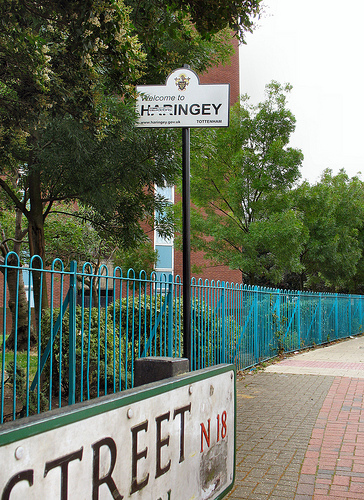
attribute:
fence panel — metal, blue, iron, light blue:
[4, 244, 363, 430]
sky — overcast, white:
[236, 0, 363, 210]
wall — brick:
[1, 1, 243, 349]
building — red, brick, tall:
[2, 1, 246, 355]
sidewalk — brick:
[147, 334, 363, 496]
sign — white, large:
[118, 62, 239, 136]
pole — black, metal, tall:
[178, 125, 198, 367]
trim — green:
[133, 69, 231, 129]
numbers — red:
[215, 411, 227, 443]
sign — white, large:
[5, 359, 237, 499]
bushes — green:
[37, 293, 355, 392]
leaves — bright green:
[0, 0, 267, 210]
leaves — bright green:
[186, 80, 308, 272]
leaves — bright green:
[271, 170, 362, 296]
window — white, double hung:
[149, 142, 177, 295]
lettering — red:
[200, 409, 230, 451]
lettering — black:
[139, 94, 226, 126]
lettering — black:
[3, 397, 197, 499]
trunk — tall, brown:
[20, 159, 61, 382]